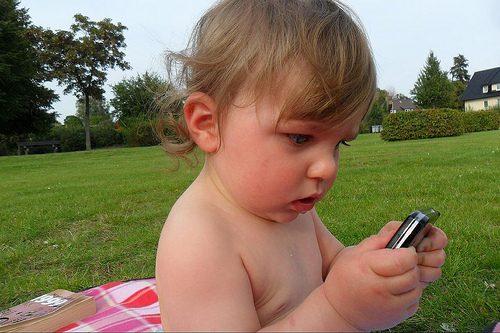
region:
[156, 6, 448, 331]
a child with brown hair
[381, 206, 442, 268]
silver and black cell phone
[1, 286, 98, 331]
a book with 1999 on the cover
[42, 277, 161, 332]
a red, white and pink cloth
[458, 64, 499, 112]
a yellow and black house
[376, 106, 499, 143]
two large green hedges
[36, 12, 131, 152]
a tall green oak tree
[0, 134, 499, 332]
a yard with green grass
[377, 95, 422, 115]
a gray and white house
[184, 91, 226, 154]
right ear of the child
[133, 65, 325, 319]
a baby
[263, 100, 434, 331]
a baby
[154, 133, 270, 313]
a baby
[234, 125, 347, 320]
a baby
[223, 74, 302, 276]
a baby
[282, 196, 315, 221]
THE BABY IS DROOLING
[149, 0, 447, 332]
THE BABY IS SHIRTLESS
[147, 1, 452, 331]
THE BABY IS SITTING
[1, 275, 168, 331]
THE BABY IS ON A BLANKET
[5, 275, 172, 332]
THE BLANKET IS ON THE GRASS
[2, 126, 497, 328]
THE GRASS IS COVERING THE GROUND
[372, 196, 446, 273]
THE BABY IS HOLDING THE PHONE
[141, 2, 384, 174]
THE BABY HAS MESSY HAIR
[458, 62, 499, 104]
THE ROOF IS BLACK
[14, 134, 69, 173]
THE BENCH IS NEXT TO THE HEDGE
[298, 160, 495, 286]
baby is holding cellphone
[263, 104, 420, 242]
baby is looking at the cellphone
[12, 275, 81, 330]
1999 title of the book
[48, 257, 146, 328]
blanket is red and white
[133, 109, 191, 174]
baby has curls in hair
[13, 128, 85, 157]
bench next to tree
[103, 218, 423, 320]
baby is sitting on the blanket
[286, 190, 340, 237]
baby has drowl on lip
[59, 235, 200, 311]
blanket is in the grass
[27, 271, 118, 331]
book is on the blanket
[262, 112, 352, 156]
the eyes of the baby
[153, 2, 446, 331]
the baby looks at the phone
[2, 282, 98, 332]
a book on the blanket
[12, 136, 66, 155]
a bench on the lawn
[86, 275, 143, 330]
a checkered blanket on the grass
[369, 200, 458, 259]
a phon in the babies hands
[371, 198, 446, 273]
a black cell phone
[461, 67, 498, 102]
a black roof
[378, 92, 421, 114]
a home with a grey roof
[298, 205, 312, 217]
the drowl on the babies lips